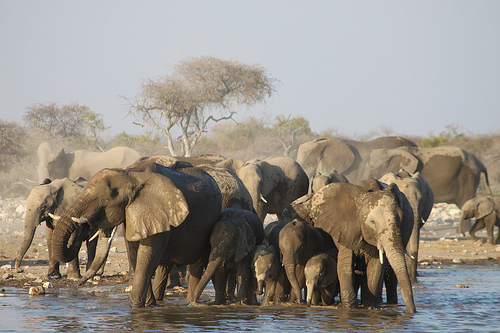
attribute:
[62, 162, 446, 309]
elephants — group, different, small, large, drinking, bathing, young, baby, herd, wet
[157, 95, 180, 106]
leaves — brown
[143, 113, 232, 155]
tree — brown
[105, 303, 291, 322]
water — body, brown, muddy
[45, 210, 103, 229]
tusks — white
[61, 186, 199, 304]
elephant — gray, youn, young, adult, wet, brown, baby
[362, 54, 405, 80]
sky — blue, hazy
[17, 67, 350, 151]
trees — tall, bare, african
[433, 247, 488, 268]
ground — rocky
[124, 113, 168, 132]
branches — gnarled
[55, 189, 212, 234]
elephant\ — wet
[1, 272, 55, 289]
rocks — dry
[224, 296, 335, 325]
mud — wet